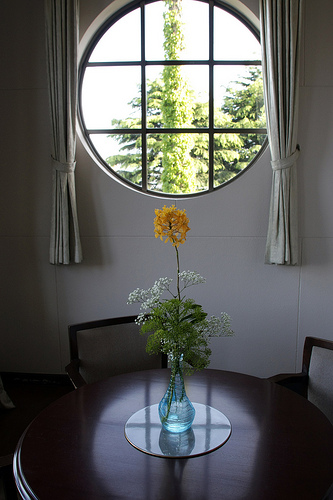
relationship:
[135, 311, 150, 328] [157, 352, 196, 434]
baby breath in flower case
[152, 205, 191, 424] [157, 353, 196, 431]
flower in vase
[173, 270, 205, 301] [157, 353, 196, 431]
flower in vase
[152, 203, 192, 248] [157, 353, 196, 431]
yellow bloom in vase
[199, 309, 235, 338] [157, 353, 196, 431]
flower in vase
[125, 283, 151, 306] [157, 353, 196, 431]
flower in vase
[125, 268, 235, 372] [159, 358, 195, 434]
baby breath in vase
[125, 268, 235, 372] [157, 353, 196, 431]
baby breath in vase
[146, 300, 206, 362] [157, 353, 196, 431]
filler in vase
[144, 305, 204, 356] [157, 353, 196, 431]
plant in vase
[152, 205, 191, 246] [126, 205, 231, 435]
yellow bloom of flower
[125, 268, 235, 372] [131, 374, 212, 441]
baby breath in vase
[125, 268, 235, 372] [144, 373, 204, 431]
baby breath are inside vase